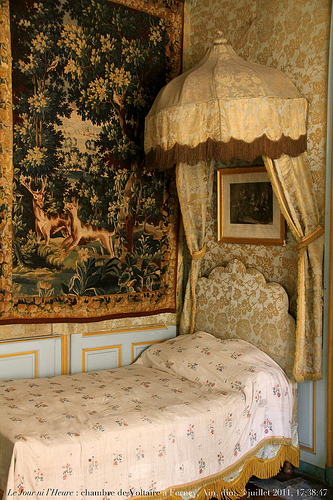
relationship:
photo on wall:
[214, 164, 288, 246] [185, 2, 331, 468]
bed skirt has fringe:
[149, 425, 304, 498] [189, 447, 303, 499]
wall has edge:
[71, 319, 177, 377] [82, 324, 170, 338]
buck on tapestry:
[13, 171, 77, 253] [3, 1, 185, 325]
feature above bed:
[139, 27, 310, 174] [0, 256, 304, 499]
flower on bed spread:
[214, 362, 226, 375] [2, 330, 296, 499]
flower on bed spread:
[39, 430, 53, 442] [2, 330, 296, 499]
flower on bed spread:
[132, 443, 146, 462] [2, 330, 296, 499]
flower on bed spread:
[80, 391, 94, 402] [2, 330, 296, 499]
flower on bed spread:
[223, 412, 236, 431] [2, 330, 296, 499]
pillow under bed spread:
[141, 330, 277, 394] [2, 330, 296, 499]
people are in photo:
[233, 185, 271, 215] [214, 164, 288, 246]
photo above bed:
[214, 164, 288, 246] [0, 256, 304, 499]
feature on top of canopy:
[139, 27, 310, 174] [142, 24, 326, 386]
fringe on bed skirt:
[189, 447, 303, 499] [149, 425, 304, 498]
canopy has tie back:
[142, 24, 326, 386] [293, 224, 325, 253]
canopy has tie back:
[142, 24, 326, 386] [191, 238, 209, 260]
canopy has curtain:
[142, 24, 326, 386] [256, 138, 325, 383]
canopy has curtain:
[142, 24, 326, 386] [169, 145, 214, 335]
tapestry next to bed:
[3, 1, 185, 325] [0, 256, 304, 499]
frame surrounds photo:
[212, 164, 287, 249] [214, 164, 288, 246]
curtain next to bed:
[256, 138, 325, 383] [0, 256, 304, 499]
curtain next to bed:
[169, 145, 214, 335] [0, 256, 304, 499]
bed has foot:
[0, 256, 304, 499] [0, 425, 30, 500]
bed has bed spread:
[0, 256, 304, 499] [2, 330, 296, 499]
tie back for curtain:
[293, 224, 325, 253] [256, 138, 325, 383]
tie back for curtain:
[191, 238, 209, 260] [169, 145, 214, 335]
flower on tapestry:
[76, 247, 91, 264] [3, 1, 185, 325]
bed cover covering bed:
[1, 333, 300, 498] [0, 256, 304, 499]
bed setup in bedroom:
[0, 256, 304, 499] [1, 1, 314, 498]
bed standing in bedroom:
[0, 256, 304, 499] [1, 331, 298, 498]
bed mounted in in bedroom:
[0, 256, 304, 499] [1, 1, 314, 498]